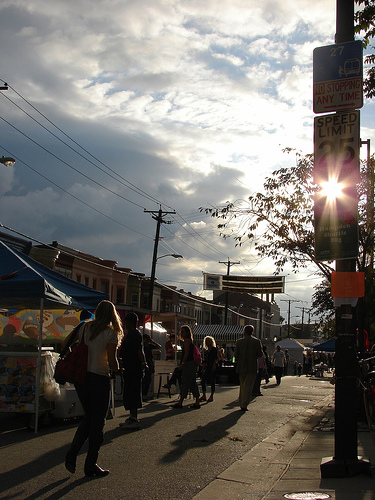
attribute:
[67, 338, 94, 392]
bag — red, big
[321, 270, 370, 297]
sign — orange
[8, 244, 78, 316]
tent — blue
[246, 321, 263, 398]
man — walking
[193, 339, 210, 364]
backpack — pink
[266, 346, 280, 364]
shirt — white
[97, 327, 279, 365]
people — walking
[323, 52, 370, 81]
sign — blue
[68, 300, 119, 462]
lady — walking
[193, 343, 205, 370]
bag — pink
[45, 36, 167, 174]
sky — cloudy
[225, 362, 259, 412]
pants — tan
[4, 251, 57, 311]
canopy — blue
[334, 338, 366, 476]
pole — wooden